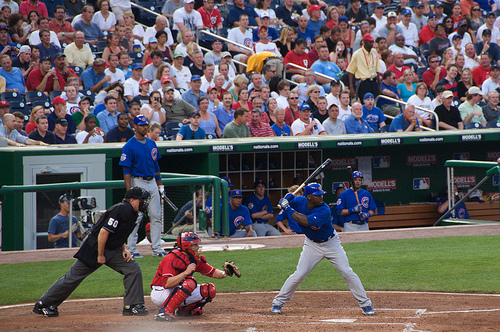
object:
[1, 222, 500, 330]
field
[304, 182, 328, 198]
hat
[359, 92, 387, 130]
man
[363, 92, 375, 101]
hat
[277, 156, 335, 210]
baseball bat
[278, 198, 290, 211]
hand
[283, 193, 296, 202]
hand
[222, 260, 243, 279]
mitt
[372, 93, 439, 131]
pole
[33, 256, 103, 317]
leg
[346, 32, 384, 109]
man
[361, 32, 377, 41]
hat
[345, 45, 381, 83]
shirt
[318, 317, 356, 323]
home plate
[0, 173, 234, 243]
pole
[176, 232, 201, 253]
helmet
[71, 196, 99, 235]
camera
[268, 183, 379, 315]
ball player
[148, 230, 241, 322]
ball player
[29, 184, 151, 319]
ball player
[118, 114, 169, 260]
ball player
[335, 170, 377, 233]
ball player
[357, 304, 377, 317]
shoe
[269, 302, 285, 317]
shoe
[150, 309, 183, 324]
shoe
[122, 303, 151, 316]
shoe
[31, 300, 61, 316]
shoe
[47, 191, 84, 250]
man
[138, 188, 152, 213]
face guard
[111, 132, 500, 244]
dugout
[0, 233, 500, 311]
grass